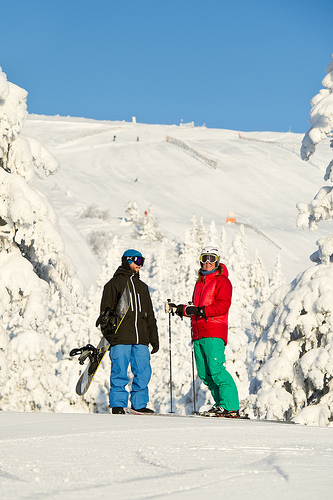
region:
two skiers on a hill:
[64, 239, 265, 423]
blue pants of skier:
[108, 340, 158, 417]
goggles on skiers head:
[124, 253, 148, 263]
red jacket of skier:
[190, 268, 236, 340]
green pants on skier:
[187, 330, 240, 419]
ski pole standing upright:
[161, 297, 180, 418]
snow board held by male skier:
[62, 285, 131, 399]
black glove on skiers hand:
[183, 304, 208, 318]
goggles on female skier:
[199, 250, 219, 265]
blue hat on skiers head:
[123, 249, 142, 261]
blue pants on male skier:
[107, 342, 162, 414]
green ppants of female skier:
[184, 334, 246, 416]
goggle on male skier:
[124, 255, 144, 265]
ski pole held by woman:
[164, 298, 179, 414]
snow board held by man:
[62, 285, 135, 403]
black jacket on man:
[98, 266, 162, 359]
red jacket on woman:
[175, 269, 231, 345]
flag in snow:
[225, 216, 236, 225]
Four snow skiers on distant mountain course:
[54, 116, 280, 227]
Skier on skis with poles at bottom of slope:
[164, 244, 299, 425]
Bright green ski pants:
[187, 336, 249, 419]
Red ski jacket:
[173, 263, 233, 345]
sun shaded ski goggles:
[197, 252, 221, 264]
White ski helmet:
[199, 245, 221, 255]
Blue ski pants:
[107, 343, 152, 411]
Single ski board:
[69, 280, 133, 399]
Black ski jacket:
[97, 266, 161, 346]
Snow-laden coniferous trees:
[0, 63, 76, 369]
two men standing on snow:
[71, 241, 251, 433]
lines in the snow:
[43, 436, 303, 499]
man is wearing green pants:
[193, 337, 246, 417]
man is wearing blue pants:
[105, 343, 153, 410]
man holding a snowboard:
[68, 287, 132, 396]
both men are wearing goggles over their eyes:
[122, 245, 221, 273]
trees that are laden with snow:
[1, 132, 332, 427]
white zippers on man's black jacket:
[99, 269, 160, 344]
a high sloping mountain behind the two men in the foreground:
[15, 111, 318, 419]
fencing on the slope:
[162, 132, 220, 171]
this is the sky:
[146, 3, 234, 55]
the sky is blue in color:
[231, 3, 312, 87]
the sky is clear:
[114, 21, 256, 69]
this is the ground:
[140, 149, 179, 191]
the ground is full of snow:
[119, 425, 212, 494]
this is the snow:
[225, 193, 266, 213]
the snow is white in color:
[199, 186, 246, 203]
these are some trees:
[3, 120, 89, 335]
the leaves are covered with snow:
[249, 285, 292, 348]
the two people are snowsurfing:
[68, 238, 256, 420]